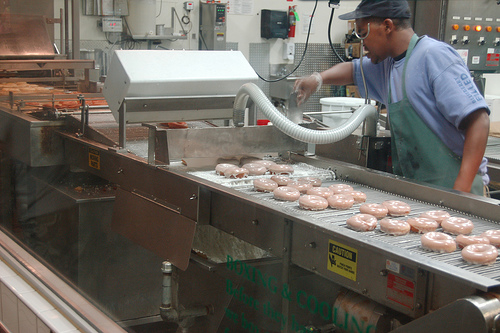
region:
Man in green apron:
[291, 1, 491, 195]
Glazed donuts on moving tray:
[212, 160, 497, 265]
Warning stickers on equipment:
[323, 236, 417, 312]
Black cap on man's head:
[337, 0, 417, 62]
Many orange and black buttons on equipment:
[433, 2, 498, 69]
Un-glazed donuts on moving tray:
[0, 77, 112, 114]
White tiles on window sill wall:
[0, 259, 92, 331]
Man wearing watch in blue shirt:
[289, 2, 489, 195]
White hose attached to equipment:
[231, 82, 379, 154]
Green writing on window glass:
[213, 253, 400, 331]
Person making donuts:
[283, 3, 498, 213]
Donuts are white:
[196, 122, 496, 272]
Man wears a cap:
[280, 3, 498, 208]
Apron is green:
[371, 59, 489, 196]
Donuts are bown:
[2, 73, 109, 121]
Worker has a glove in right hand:
[285, 1, 498, 195]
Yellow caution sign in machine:
[311, 234, 366, 291]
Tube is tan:
[219, 76, 381, 153]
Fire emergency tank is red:
[281, 1, 303, 42]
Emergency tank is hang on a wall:
[280, 4, 304, 42]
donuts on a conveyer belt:
[302, 178, 414, 224]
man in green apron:
[353, 2, 488, 184]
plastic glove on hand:
[290, 68, 331, 105]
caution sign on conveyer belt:
[319, 234, 370, 286]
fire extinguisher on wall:
[281, 5, 307, 43]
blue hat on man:
[330, 1, 415, 27]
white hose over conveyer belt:
[254, 90, 376, 149]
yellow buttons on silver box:
[449, 16, 498, 41]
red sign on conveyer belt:
[380, 266, 421, 311]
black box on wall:
[257, 8, 289, 44]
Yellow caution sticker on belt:
[314, 222, 384, 324]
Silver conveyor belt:
[219, 164, 428, 282]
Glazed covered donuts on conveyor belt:
[256, 147, 443, 282]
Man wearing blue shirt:
[368, 61, 443, 165]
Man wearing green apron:
[364, 91, 434, 175]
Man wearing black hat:
[329, 7, 426, 29]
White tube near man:
[227, 70, 417, 166]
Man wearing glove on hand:
[286, 55, 337, 150]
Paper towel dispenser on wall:
[252, 5, 298, 132]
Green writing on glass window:
[199, 207, 335, 328]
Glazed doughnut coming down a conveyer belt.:
[417, 230, 454, 255]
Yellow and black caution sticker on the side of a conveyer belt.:
[327, 236, 358, 281]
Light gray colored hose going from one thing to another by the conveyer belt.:
[231, 82, 378, 144]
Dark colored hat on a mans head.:
[338, 0, 413, 21]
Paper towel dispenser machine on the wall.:
[260, 7, 288, 37]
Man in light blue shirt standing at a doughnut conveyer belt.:
[292, 1, 491, 198]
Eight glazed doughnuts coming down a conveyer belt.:
[346, 200, 471, 252]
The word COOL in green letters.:
[297, 289, 345, 329]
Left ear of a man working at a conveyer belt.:
[380, 15, 394, 34]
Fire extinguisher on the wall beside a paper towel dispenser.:
[290, 12, 300, 38]